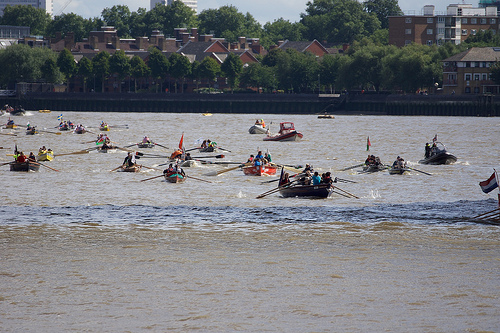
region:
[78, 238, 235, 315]
the water is calm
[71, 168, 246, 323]
the water is calm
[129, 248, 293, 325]
the water is calm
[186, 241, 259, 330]
the water is calm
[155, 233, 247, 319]
the water is calm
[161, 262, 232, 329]
the water is calm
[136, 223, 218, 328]
the water is calm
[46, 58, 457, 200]
boats in the water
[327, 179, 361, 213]
paddles in the water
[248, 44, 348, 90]
trees in the distance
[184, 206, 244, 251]
ripples in the water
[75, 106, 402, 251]
many people in the water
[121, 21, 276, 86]
houses in the background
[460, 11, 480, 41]
windows on the building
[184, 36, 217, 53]
roof of the building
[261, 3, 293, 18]
sky above the land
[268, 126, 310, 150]
boat in the water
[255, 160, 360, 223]
boat full of people in water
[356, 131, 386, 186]
boat with red and blue flag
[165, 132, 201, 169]
boat with orange flag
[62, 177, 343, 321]
lake with gray water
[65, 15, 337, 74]
neighborhood behind gray lake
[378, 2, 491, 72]
multi level brick building in background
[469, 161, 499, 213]
red white and blue flag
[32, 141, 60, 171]
small yellow boat on left side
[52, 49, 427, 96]
row of decorative trees behind lake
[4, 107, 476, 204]
many boats in the water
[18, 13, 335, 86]
Houses surrounded by trees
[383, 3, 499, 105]
Apartment buildings in the background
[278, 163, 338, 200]
People rowing in boats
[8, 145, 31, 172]
A man in a red shirt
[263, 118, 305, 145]
A boat with a red cabin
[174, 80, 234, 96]
Cars parked under the trees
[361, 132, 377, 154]
A red flag in the water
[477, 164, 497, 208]
A flag of red, white, and blue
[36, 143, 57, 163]
A yellow boat on the water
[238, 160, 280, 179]
A red and white boat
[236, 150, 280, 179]
red boat with many people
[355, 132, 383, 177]
boat with orange and blue flag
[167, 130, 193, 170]
small boat with orange flag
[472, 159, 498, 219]
red white blue flag on right side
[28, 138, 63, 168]
small yellow boat on left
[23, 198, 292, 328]
gray and brown lake water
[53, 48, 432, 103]
row of trees in background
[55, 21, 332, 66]
row of houses beyond trees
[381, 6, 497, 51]
brick background building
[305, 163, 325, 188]
man in blue shirt in front of boat